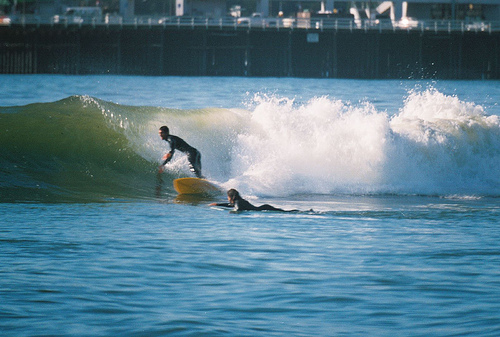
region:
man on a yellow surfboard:
[156, 125, 226, 193]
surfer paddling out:
[209, 186, 325, 216]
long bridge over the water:
[6, 28, 496, 80]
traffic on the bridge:
[10, 5, 300, 22]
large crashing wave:
[5, 93, 499, 188]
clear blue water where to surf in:
[1, 74, 497, 331]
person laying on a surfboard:
[208, 191, 325, 213]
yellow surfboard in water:
[172, 177, 217, 193]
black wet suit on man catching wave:
[165, 135, 203, 173]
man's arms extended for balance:
[158, 149, 177, 169]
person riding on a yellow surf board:
[150, 122, 229, 200]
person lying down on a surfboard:
[197, 186, 326, 222]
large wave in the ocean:
[0, 75, 498, 210]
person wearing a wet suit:
[147, 121, 227, 201]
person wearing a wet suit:
[202, 183, 322, 218]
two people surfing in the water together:
[150, 115, 332, 222]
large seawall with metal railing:
[0, 9, 498, 81]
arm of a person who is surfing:
[153, 139, 175, 175]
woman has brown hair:
[203, 184, 328, 224]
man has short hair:
[155, 120, 232, 200]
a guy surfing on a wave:
[148, 117, 209, 204]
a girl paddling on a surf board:
[225, 190, 300, 225]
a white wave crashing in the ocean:
[257, 93, 462, 198]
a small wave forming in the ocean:
[37, 85, 145, 193]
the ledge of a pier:
[135, 7, 221, 73]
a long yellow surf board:
[167, 166, 212, 209]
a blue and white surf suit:
[170, 134, 212, 180]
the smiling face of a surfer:
[152, 124, 179, 144]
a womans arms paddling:
[201, 198, 231, 217]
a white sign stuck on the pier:
[295, 20, 337, 52]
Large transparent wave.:
[0, 94, 498, 221]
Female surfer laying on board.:
[207, 187, 320, 222]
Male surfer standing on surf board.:
[155, 125, 230, 198]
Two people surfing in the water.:
[0, 71, 499, 332]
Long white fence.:
[2, 11, 498, 36]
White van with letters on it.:
[51, 5, 106, 25]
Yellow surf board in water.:
[172, 174, 225, 200]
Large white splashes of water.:
[228, 86, 498, 197]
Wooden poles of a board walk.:
[1, 25, 498, 79]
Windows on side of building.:
[430, 1, 489, 21]